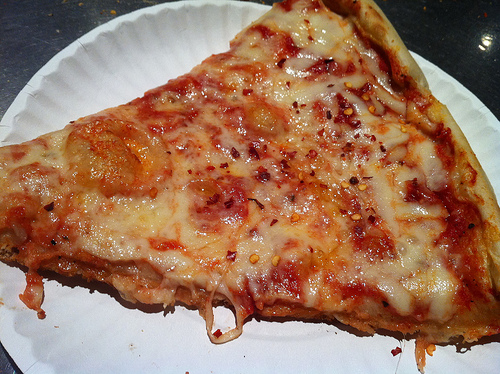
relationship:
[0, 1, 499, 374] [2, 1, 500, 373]
cheese on plate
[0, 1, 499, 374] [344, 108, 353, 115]
cheese has spices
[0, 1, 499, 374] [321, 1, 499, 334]
cheese has a crust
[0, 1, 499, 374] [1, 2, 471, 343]
cheese has cheese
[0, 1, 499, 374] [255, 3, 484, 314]
cheese has red sauce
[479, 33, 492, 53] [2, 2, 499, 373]
light shining on surface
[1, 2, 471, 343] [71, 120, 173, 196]
cheese has a bubble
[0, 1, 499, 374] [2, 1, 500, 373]
cheese on a plate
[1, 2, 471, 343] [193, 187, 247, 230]
cheese between pepperoni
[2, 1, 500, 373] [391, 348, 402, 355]
plate has a crumb